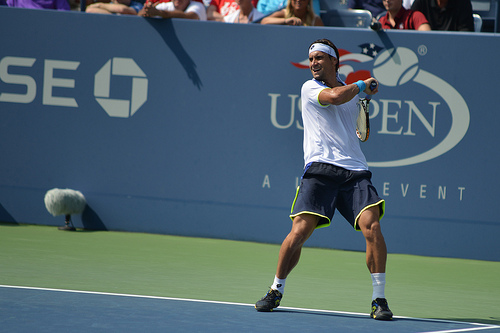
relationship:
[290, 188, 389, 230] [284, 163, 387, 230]
stripe on shorts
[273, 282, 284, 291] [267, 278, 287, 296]
symbol on sock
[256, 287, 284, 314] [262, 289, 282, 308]
sneaker with laces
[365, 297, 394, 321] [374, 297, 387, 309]
sneaker with laces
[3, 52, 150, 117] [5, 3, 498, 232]
word on background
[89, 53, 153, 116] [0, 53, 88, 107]
octagon in letters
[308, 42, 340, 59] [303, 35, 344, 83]
headband on head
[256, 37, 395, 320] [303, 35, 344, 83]
man has head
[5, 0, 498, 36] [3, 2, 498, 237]
spectators sitting in stand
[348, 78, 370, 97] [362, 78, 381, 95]
armband on hand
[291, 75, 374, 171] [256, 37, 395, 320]
t-shirt on man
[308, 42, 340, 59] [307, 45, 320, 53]
headband with emblem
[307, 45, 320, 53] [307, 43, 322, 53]
emblem on emblem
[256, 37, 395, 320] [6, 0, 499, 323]
man playing tennis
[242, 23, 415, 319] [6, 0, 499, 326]
man in competition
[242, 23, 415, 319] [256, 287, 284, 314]
man has sneaker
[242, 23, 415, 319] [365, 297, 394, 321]
man has sneaker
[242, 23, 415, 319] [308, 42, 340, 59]
man wearing headband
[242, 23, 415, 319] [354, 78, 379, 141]
man has racket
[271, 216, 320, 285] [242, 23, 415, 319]
leg on man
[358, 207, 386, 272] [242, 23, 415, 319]
leg on man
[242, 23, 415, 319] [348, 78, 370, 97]
man wearing armband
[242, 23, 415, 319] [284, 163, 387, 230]
man wearing shorts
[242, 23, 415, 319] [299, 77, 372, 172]
man wearing t-shirt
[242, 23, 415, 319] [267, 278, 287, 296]
man wearing sock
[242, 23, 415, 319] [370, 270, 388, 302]
man wearing sock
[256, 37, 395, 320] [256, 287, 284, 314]
man wearing sneaker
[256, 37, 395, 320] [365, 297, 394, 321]
man wearing sneaker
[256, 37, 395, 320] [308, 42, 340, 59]
man wearing headband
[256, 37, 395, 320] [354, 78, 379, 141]
man holding racket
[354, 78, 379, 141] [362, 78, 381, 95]
racket in hand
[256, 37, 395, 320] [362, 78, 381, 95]
man has hand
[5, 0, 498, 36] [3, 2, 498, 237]
people in stands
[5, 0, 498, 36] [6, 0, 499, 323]
people watching match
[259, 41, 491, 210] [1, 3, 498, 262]
name on wall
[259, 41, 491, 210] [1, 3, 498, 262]
name written on wall